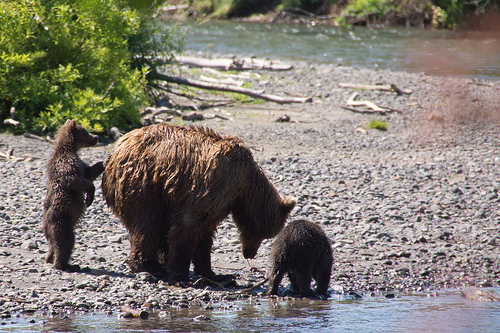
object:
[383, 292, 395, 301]
rocks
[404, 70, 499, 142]
dirt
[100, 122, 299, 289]
bear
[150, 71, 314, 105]
trunk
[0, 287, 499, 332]
water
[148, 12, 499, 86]
water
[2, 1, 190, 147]
bush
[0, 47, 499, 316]
ground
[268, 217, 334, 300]
animal